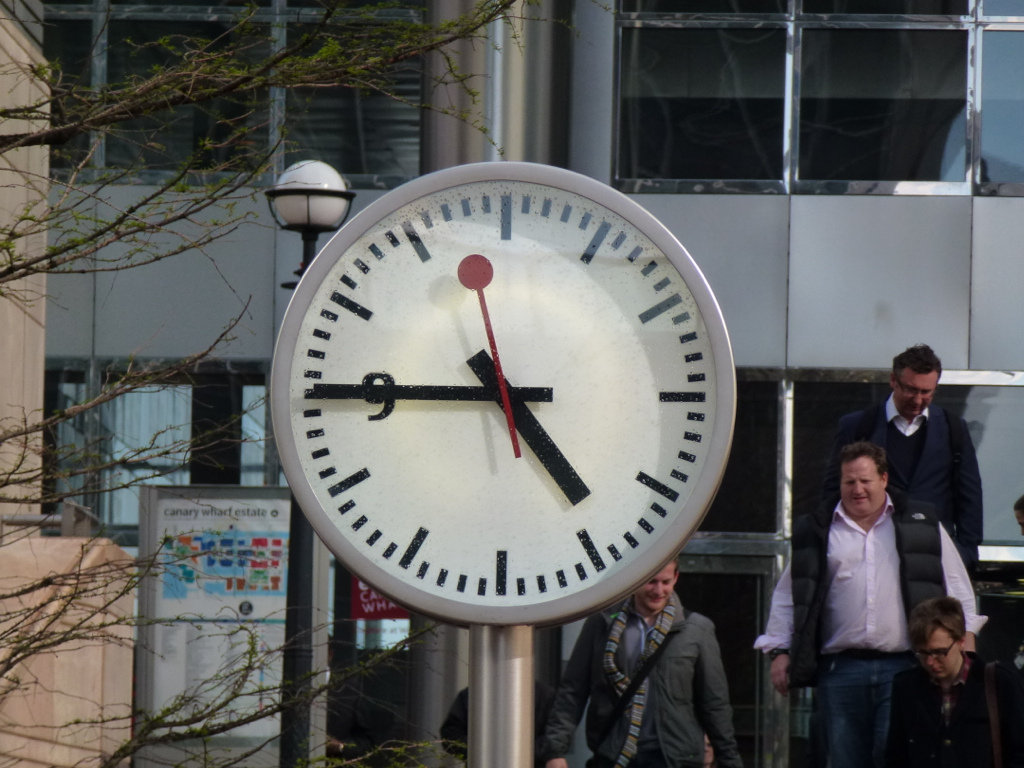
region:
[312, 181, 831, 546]
a view of clock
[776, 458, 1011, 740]
a view of man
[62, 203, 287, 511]
a view of windows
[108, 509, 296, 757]
a view of stems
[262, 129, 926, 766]
a clock in the stand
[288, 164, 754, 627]
Black and white clock.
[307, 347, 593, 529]
Black hands on a clock.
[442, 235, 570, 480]
Red hand on a clock.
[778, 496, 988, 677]
Black vest on a man.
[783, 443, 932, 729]
Man walking by a building.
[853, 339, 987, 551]
Man wearing a jacket.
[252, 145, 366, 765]
Light post by a building.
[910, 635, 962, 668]
Glasses on a person.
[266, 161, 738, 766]
A large metal clock.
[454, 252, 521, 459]
The second hand is red.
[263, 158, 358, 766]
The lamp has a circular bulb.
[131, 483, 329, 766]
A large informational sign with a map.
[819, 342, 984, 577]
The man is wearing a blue blazer.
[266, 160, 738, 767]
The clock is attached to a metal pole.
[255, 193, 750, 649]
The clock is black and white.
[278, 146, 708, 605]
A clock attached to the pole.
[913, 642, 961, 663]
The person is wearing glasses.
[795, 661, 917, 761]
The man is wearing blue jeans.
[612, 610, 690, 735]
A scarf around the man neck.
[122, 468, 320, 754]
A white sign by building.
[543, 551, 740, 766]
A person walking on a sidewalk.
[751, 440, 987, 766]
A person walking on a sidewalk.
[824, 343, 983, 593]
A person walking on a sidewalk.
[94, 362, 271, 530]
A window on a building.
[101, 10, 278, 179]
A window on a building.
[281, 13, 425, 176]
A window on a building.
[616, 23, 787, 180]
A window on a building.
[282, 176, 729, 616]
the clock face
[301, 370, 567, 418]
the minute hand of the clock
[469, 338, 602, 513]
the hour hand of the clock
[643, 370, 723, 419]
the 3 o'clock position of theclock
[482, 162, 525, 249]
the 12 o'clock position of theclock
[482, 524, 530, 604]
the 6 o'clock position of theclock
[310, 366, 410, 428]
the 9 o'clock position of theclock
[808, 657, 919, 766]
the mans legs below torso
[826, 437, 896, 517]
the mans head above shoulders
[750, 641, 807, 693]
the mans hand at end of arm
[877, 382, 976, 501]
window on the building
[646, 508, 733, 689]
window on the building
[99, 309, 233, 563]
window on the building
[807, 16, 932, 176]
window on the building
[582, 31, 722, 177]
window on the building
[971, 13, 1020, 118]
window on the building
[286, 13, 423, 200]
window on the building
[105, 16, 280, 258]
window on the building